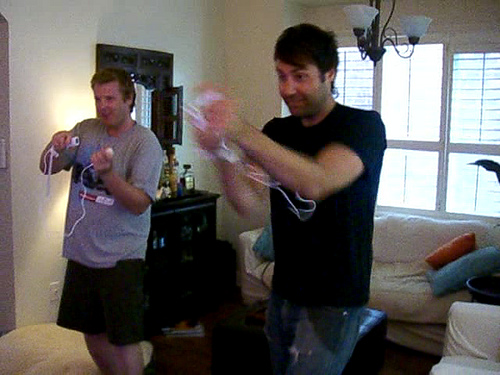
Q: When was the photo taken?
A: Daytime.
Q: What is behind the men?
A: A couch.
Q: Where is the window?
A: On the wall.